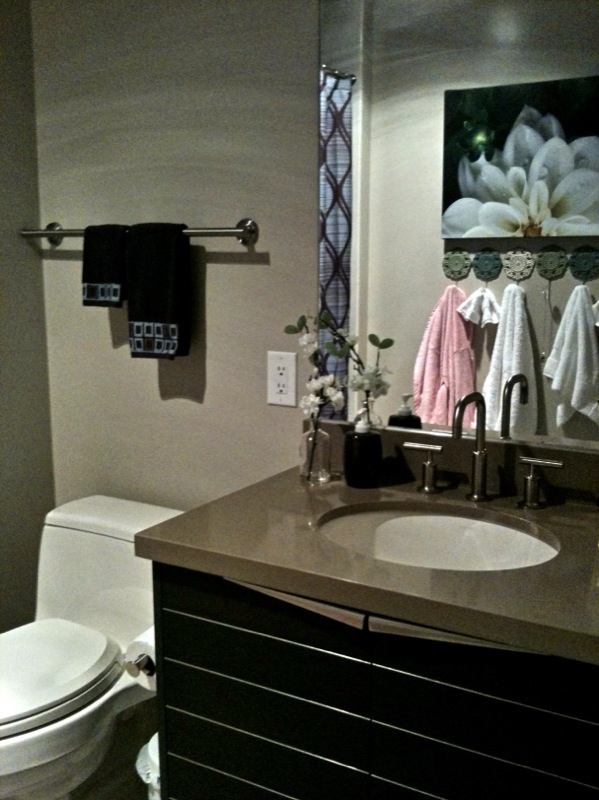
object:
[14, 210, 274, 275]
rack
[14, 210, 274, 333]
towels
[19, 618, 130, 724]
lid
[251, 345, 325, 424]
outlet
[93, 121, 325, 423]
wall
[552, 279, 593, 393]
towel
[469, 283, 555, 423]
towel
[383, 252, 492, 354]
towel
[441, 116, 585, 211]
picture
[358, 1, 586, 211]
wall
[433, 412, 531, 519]
faucet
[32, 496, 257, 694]
toilet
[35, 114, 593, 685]
bathroom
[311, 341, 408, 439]
flower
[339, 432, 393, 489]
vase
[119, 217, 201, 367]
towel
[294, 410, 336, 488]
jar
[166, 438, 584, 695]
counter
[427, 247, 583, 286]
plastic lid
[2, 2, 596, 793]
bathroom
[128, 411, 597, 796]
vanity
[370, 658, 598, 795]
drawers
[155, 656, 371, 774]
drawers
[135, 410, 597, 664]
countertop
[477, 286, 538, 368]
towel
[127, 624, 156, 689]
tissue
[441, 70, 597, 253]
picture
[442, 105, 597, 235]
flower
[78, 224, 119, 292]
towel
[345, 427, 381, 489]
black bottle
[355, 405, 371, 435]
white pump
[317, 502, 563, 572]
sink